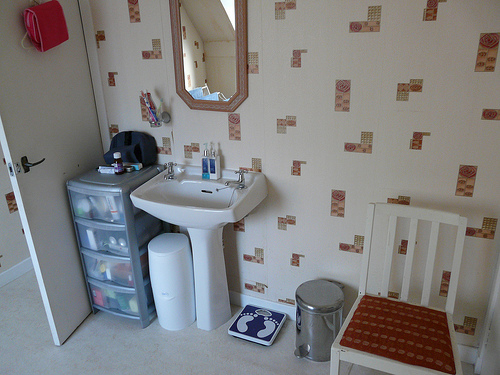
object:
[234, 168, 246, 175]
knob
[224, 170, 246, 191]
faucet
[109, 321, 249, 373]
ground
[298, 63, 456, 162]
wallpaper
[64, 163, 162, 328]
cabinet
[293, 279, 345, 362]
garbage can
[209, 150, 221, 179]
bottle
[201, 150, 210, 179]
bottle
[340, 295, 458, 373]
pattern seat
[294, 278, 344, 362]
can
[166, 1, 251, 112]
mirror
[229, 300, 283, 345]
scale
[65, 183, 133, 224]
drawer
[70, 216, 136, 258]
drawer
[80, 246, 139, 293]
drawer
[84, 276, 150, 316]
drawer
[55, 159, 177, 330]
storage unit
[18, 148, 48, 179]
wine glass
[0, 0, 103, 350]
door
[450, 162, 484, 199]
pattern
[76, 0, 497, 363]
wall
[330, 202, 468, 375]
chair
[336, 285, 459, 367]
red cushion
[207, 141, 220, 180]
soap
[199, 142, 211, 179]
soap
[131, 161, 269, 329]
sink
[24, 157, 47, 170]
door handle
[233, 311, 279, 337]
footprints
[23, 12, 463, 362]
storage unit